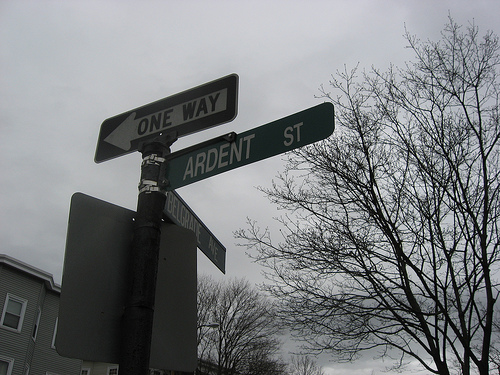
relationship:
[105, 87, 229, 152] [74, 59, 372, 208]
arrow on sign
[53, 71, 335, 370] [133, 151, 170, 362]
signs on pole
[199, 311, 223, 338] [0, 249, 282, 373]
light near houses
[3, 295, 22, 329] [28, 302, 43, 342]
window with white trim